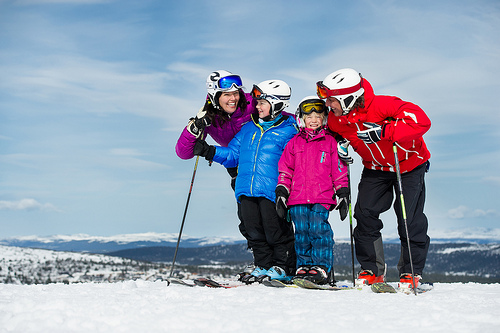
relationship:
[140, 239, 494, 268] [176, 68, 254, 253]
mountain behind female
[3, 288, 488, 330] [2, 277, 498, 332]
footprints on snow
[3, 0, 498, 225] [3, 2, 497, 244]
clouds in sky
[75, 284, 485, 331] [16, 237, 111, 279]
tracks on snow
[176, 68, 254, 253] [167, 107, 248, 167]
female wears jacket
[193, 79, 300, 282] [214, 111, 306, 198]
boy wears blue jacket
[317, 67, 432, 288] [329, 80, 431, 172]
adult wears jacket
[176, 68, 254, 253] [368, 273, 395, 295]
female on skis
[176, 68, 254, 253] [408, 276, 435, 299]
female on skis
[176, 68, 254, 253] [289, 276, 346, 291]
female on skis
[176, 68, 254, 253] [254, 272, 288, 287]
female on skis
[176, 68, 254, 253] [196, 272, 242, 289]
female on skis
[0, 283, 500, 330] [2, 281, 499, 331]
snow in ground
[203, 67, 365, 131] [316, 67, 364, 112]
helmets in head